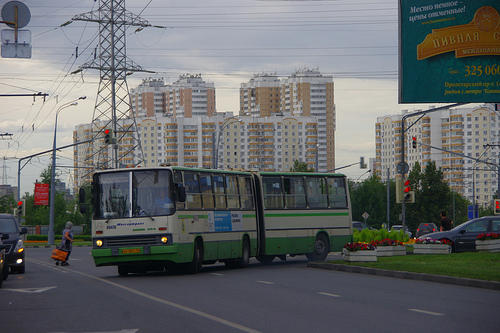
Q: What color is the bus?
A: Green, white.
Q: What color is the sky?
A: Grey.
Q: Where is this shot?
A: Street.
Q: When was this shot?
A: Daytime.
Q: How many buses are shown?
A: 1.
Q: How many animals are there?
A: 0.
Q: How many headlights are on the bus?
A: 2.